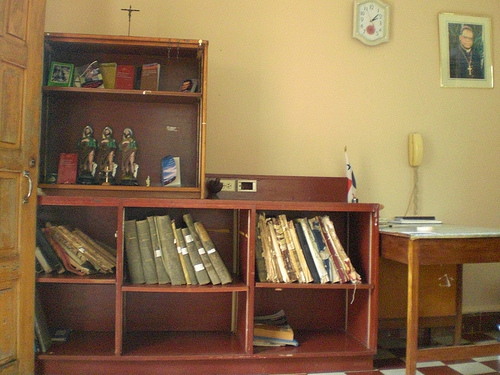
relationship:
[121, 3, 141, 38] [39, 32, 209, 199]
cross on shelf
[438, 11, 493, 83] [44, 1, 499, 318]
picture hanging on wall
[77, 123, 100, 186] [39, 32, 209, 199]
religious statue on shelf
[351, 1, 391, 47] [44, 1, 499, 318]
clock hanging on wall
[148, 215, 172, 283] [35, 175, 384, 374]
book sitting on shelf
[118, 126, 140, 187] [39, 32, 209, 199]
figure on shelf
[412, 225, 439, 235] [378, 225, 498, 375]
white top on top of wooden desk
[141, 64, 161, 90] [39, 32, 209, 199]
book on shelf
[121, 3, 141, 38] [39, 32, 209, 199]
cross on top of shelf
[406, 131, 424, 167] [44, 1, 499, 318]
telephone hanging on wall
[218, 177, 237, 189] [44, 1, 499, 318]
outlet on wall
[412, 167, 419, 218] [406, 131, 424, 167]
cord on telephone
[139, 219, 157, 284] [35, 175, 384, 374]
book on shelf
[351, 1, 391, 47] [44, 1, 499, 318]
clock mounted on wall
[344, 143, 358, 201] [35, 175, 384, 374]
flag on bookcase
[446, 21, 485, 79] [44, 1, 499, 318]
photo mounted on wall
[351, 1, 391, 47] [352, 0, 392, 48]
clock with white frame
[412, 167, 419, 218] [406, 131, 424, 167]
cord hanging from telephone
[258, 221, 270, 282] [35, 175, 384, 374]
book sitting on shelf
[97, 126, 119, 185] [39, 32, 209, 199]
statue on shelf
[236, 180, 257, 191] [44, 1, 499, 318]
outlet mounted on wall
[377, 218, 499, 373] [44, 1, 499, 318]
desk against wall